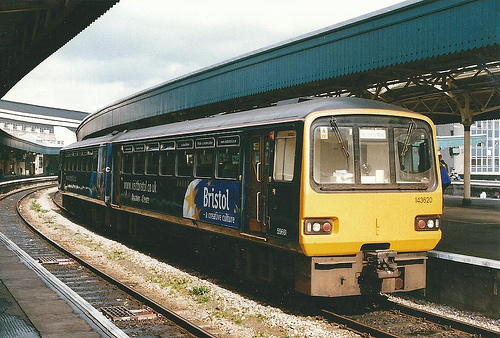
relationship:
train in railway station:
[44, 101, 448, 309] [1, 2, 498, 337]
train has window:
[44, 101, 448, 309] [216, 136, 242, 181]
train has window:
[44, 101, 448, 309] [193, 138, 216, 178]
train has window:
[44, 101, 448, 309] [174, 139, 195, 179]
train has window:
[44, 101, 448, 309] [160, 142, 176, 176]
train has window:
[44, 101, 448, 309] [148, 142, 159, 177]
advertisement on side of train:
[119, 171, 243, 224] [44, 101, 448, 309]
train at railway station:
[44, 101, 448, 309] [1, 2, 498, 337]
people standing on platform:
[7, 149, 33, 178] [2, 133, 60, 191]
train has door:
[44, 101, 448, 309] [241, 131, 276, 230]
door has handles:
[241, 131, 276, 230] [251, 158, 263, 222]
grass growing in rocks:
[165, 271, 216, 305] [105, 228, 321, 335]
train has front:
[44, 101, 448, 309] [298, 97, 444, 300]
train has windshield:
[44, 101, 448, 309] [308, 115, 437, 193]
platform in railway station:
[2, 133, 60, 191] [1, 2, 498, 337]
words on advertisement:
[199, 184, 234, 208] [119, 171, 243, 224]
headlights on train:
[304, 209, 444, 234] [44, 101, 448, 309]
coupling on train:
[308, 247, 430, 296] [44, 101, 448, 309]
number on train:
[413, 194, 435, 206] [44, 101, 448, 309]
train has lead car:
[44, 101, 448, 309] [108, 96, 453, 305]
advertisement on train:
[119, 171, 243, 224] [44, 101, 448, 309]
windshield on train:
[308, 115, 437, 193] [44, 101, 448, 309]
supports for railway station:
[375, 72, 494, 210] [1, 2, 498, 337]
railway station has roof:
[1, 2, 498, 337] [76, 3, 499, 138]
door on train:
[241, 131, 276, 230] [44, 101, 448, 309]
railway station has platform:
[1, 2, 498, 337] [2, 133, 60, 191]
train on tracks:
[44, 101, 448, 309] [1, 174, 452, 337]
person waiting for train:
[435, 146, 453, 200] [44, 101, 448, 309]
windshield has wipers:
[308, 115, 437, 193] [327, 115, 419, 165]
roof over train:
[76, 3, 499, 138] [44, 101, 448, 309]